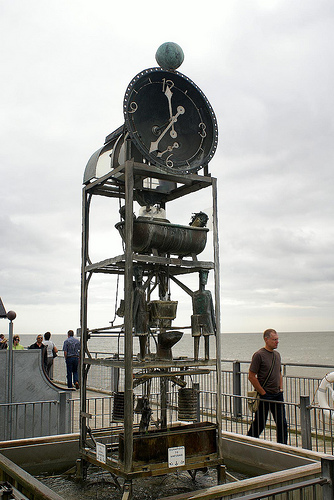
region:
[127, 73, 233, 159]
A clock on the object.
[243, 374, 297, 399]
A man with his hands in pocket.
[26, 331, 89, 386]
People on the boat.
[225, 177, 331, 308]
The sky is full of clouds.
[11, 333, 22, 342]
The lady is wearing sunglasses.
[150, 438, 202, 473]
A sign on the exhibit.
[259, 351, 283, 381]
The shoulder straps over the man shoulder.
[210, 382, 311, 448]
A railing around the structure.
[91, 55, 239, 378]
A metal structure with a clock.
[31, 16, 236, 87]
The sky has clouds.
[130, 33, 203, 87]
a ball on top of the clock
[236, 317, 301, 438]
a man is walking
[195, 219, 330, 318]
the sky is overcast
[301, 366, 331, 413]
a life preserver attached to the fence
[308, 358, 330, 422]
the life preserver is white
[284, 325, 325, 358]
the water is calm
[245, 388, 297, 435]
the pants are black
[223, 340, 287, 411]
the man is wearing a shoulder bag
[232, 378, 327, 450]
the fence is grey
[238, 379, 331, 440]
the fence is made of metal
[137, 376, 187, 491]
this is a tower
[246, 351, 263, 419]
this is a man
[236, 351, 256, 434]
this is a bag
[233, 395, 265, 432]
this is a crossbody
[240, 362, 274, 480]
the bag is canvas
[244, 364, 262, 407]
this is an elbow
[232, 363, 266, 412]
this is an arm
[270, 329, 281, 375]
this is a head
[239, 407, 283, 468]
this is a pair of pants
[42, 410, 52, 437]
this is a metal enclosure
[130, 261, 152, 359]
the metal statue of a person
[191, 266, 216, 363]
the metal statue of a person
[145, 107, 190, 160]
the white hand of the clock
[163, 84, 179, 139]
the white hand of the clock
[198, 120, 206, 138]
the white number 3 of the clock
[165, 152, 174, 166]
the white number 6 of the clock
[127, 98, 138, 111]
the white number 9 of the clock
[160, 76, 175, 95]
the white number 12 of the clock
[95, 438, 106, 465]
the black and white sign on the clock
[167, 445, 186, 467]
the black and white sign on the clock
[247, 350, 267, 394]
the arm of the man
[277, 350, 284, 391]
the arm of the man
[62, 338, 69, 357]
the arm of the man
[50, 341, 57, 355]
the arm of the woman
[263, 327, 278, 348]
the head of the man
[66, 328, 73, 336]
the head of the man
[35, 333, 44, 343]
the head of the man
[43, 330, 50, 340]
the head of the woman